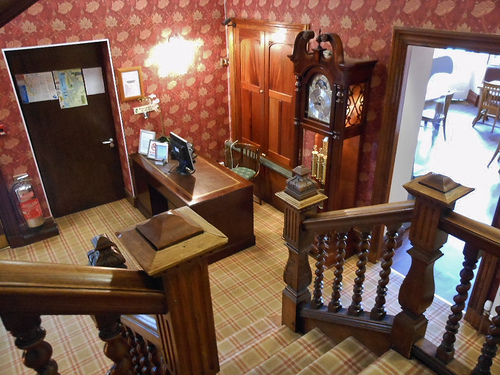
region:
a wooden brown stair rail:
[274, 160, 458, 335]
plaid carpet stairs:
[217, 288, 403, 373]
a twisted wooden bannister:
[326, 225, 347, 315]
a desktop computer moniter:
[163, 132, 200, 175]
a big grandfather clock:
[287, 66, 373, 230]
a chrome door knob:
[101, 134, 118, 150]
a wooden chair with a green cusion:
[221, 128, 270, 198]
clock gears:
[305, 135, 337, 205]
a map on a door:
[45, 66, 94, 111]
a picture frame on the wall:
[116, 66, 150, 106]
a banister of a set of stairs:
[314, 199, 401, 319]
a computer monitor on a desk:
[166, 130, 197, 177]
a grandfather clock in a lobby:
[288, 27, 360, 170]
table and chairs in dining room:
[430, 85, 497, 155]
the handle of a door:
[99, 133, 119, 150]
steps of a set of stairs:
[243, 330, 376, 372]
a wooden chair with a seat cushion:
[223, 137, 265, 184]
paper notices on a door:
[22, 68, 107, 106]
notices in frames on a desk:
[134, 127, 169, 169]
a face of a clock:
[304, 87, 336, 120]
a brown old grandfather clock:
[276, 26, 370, 261]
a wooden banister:
[280, 159, 321, 340]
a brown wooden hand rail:
[271, 157, 462, 234]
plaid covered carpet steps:
[201, 316, 441, 373]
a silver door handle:
[97, 137, 123, 153]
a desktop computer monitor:
[163, 128, 201, 183]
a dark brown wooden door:
[11, 34, 134, 219]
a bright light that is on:
[140, 35, 212, 81]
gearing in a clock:
[308, 138, 342, 200]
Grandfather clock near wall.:
[289, 40, 362, 242]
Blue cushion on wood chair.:
[215, 139, 285, 188]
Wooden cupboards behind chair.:
[236, 70, 305, 147]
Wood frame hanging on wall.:
[114, 58, 146, 105]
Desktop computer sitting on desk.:
[168, 130, 211, 200]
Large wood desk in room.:
[131, 108, 248, 245]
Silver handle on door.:
[95, 122, 122, 162]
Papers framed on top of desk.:
[135, 123, 157, 175]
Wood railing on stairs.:
[292, 165, 459, 317]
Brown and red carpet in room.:
[230, 271, 272, 347]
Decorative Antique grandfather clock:
[285, 26, 375, 251]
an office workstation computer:
[165, 127, 198, 180]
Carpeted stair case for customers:
[210, 298, 392, 373]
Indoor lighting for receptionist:
[133, 22, 208, 87]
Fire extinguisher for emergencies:
[5, 160, 51, 222]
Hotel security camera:
[198, 10, 248, 33]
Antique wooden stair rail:
[282, 168, 453, 354]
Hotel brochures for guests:
[132, 126, 172, 169]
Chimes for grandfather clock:
[302, 137, 332, 187]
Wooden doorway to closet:
[225, 13, 317, 193]